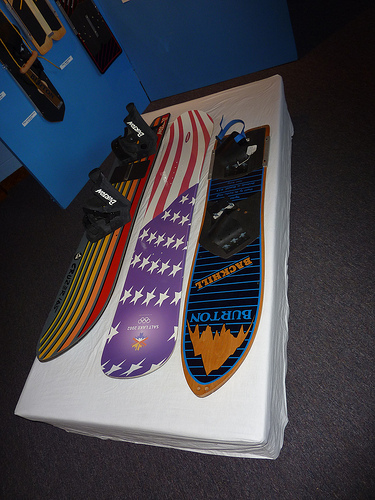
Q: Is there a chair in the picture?
A: No, there are no chairs.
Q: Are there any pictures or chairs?
A: No, there are no chairs or pictures.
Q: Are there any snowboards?
A: Yes, there is a snowboard.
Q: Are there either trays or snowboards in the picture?
A: Yes, there is a snowboard.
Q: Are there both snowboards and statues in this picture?
A: No, there is a snowboard but no statues.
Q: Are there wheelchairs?
A: No, there are no wheelchairs.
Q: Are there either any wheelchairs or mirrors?
A: No, there are no wheelchairs or mirrors.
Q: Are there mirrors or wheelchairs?
A: No, there are no wheelchairs or mirrors.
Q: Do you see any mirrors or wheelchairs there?
A: No, there are no wheelchairs or mirrors.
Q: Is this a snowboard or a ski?
A: This is a snowboard.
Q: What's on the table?
A: The snowboard is on the table.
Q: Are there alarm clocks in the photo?
A: No, there are no alarm clocks.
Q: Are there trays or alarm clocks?
A: No, there are no alarm clocks or trays.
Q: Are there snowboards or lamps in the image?
A: Yes, there is a snowboard.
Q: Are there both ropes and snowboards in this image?
A: No, there is a snowboard but no ropes.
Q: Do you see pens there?
A: No, there are no pens.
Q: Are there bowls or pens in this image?
A: No, there are no pens or bowls.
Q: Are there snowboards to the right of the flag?
A: Yes, there is a snowboard to the right of the flag.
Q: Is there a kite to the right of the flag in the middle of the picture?
A: No, there is a snowboard to the right of the flag.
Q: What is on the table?
A: The snowboard is on the table.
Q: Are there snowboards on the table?
A: Yes, there is a snowboard on the table.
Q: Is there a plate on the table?
A: No, there is a snowboard on the table.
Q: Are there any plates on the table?
A: No, there is a snowboard on the table.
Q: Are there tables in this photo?
A: Yes, there is a table.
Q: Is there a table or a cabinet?
A: Yes, there is a table.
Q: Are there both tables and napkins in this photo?
A: No, there is a table but no napkins.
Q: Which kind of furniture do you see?
A: The furniture is a table.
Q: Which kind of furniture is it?
A: The piece of furniture is a table.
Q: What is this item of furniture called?
A: This is a table.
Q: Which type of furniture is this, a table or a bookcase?
A: This is a table.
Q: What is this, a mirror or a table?
A: This is a table.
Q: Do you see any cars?
A: No, there are no cars.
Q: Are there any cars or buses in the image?
A: No, there are no cars or buses.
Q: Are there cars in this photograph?
A: No, there are no cars.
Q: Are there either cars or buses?
A: No, there are no cars or buses.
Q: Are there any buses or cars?
A: No, there are no cars or buses.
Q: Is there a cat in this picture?
A: No, there are no cats.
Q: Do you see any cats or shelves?
A: No, there are no cats or shelves.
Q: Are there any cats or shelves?
A: No, there are no cats or shelves.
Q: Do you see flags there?
A: Yes, there is a flag.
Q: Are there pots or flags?
A: Yes, there is a flag.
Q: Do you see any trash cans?
A: No, there are no trash cans.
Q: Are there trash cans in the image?
A: No, there are no trash cans.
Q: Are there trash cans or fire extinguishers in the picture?
A: No, there are no trash cans or fire extinguishers.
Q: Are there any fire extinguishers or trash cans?
A: No, there are no trash cans or fire extinguishers.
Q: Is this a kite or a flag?
A: This is a flag.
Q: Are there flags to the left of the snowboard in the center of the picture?
A: Yes, there is a flag to the left of the snowboard.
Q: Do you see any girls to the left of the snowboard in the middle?
A: No, there is a flag to the left of the snowboard.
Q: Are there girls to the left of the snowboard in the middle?
A: No, there is a flag to the left of the snowboard.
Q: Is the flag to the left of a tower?
A: No, the flag is to the left of the snowboard.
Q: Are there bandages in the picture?
A: No, there are no bandages.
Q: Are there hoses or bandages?
A: No, there are no bandages or hoses.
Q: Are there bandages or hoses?
A: No, there are no bandages or hoses.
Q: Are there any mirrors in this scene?
A: No, there are no mirrors.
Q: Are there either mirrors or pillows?
A: No, there are no mirrors or pillows.